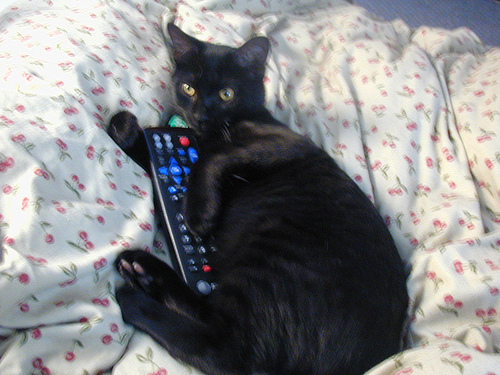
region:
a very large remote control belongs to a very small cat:
[139, 111, 243, 303]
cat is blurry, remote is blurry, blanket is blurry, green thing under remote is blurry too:
[1, 1, 498, 374]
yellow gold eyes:
[178, 76, 239, 106]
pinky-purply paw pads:
[115, 256, 151, 288]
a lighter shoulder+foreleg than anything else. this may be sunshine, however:
[179, 113, 321, 247]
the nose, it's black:
[188, 110, 213, 127]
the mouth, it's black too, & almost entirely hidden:
[192, 121, 210, 138]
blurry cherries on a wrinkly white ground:
[0, 264, 165, 372]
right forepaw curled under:
[107, 105, 143, 157]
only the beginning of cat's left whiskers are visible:
[215, 113, 239, 148]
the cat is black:
[75, 3, 421, 371]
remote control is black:
[125, 90, 240, 325]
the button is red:
[175, 125, 192, 155]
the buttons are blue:
[150, 155, 210, 200]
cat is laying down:
[90, 20, 392, 367]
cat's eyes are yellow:
[176, 71, 243, 110]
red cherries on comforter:
[4, 1, 480, 371]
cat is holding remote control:
[92, 99, 349, 283]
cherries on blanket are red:
[2, 2, 435, 322]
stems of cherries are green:
[49, 145, 79, 172]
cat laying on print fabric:
[97, 19, 412, 374]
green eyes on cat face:
[175, 79, 238, 106]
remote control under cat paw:
[137, 120, 235, 299]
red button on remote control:
[173, 132, 195, 151]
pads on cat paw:
[115, 245, 150, 281]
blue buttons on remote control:
[157, 156, 190, 190]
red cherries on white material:
[67, 225, 99, 257]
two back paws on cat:
[112, 247, 184, 338]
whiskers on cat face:
[213, 113, 238, 151]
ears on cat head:
[155, 20, 274, 69]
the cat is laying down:
[101, 15, 418, 349]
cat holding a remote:
[116, 111, 231, 291]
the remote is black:
[128, 105, 215, 285]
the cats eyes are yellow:
[155, 74, 240, 106]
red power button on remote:
[170, 123, 192, 146]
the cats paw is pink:
[94, 249, 153, 279]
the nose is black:
[181, 105, 212, 125]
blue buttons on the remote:
[139, 150, 199, 182]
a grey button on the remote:
[185, 274, 214, 296]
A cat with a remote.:
[106, 22, 409, 373]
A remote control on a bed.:
[141, 125, 222, 297]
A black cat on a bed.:
[106, 20, 408, 372]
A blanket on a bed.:
[2, 0, 498, 373]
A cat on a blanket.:
[104, 20, 411, 373]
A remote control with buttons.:
[141, 124, 214, 296]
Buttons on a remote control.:
[151, 132, 218, 296]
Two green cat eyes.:
[180, 80, 235, 102]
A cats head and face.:
[170, 42, 265, 137]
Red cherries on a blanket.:
[396, 101, 433, 131]